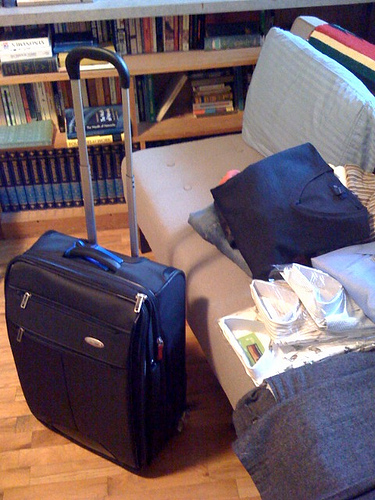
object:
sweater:
[207, 138, 370, 285]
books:
[66, 104, 131, 149]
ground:
[2, 211, 271, 498]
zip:
[129, 288, 148, 315]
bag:
[81, 330, 113, 353]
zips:
[15, 279, 32, 347]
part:
[58, 38, 138, 89]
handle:
[62, 40, 128, 93]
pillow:
[242, 27, 374, 176]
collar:
[218, 306, 283, 389]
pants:
[228, 355, 371, 497]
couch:
[118, 16, 375, 460]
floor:
[179, 457, 248, 498]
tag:
[65, 236, 123, 272]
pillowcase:
[183, 204, 255, 281]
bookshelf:
[0, 2, 348, 239]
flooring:
[4, 434, 83, 498]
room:
[4, 0, 374, 497]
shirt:
[282, 264, 364, 336]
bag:
[266, 255, 291, 283]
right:
[118, 3, 373, 498]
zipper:
[19, 292, 31, 312]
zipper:
[13, 321, 24, 345]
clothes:
[187, 143, 373, 498]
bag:
[4, 231, 186, 471]